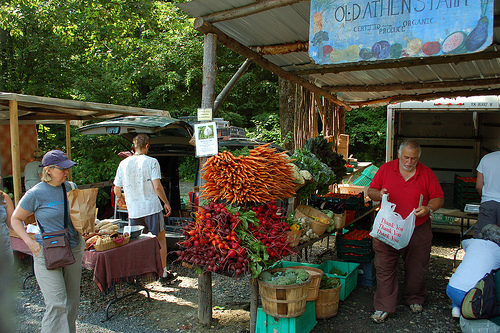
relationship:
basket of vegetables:
[256, 268, 308, 315] [258, 268, 308, 284]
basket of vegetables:
[279, 265, 321, 302] [298, 263, 320, 277]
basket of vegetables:
[311, 276, 339, 317] [320, 269, 339, 289]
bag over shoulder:
[35, 179, 76, 269] [29, 178, 77, 193]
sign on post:
[196, 105, 210, 155] [197, 31, 217, 324]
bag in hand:
[371, 192, 418, 252] [412, 202, 429, 217]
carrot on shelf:
[231, 152, 251, 171] [225, 193, 305, 211]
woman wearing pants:
[10, 147, 87, 332] [36, 246, 88, 329]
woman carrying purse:
[10, 147, 87, 329] [35, 182, 77, 271]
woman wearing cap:
[10, 147, 87, 329] [42, 149, 77, 169]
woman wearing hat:
[10, 147, 87, 329] [41, 147, 74, 167]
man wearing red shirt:
[367, 139, 444, 323] [368, 157, 443, 227]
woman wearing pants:
[10, 147, 87, 332] [29, 236, 91, 331]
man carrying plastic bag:
[357, 130, 439, 332] [369, 192, 421, 257]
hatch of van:
[74, 111, 197, 146] [93, 141, 199, 219]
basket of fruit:
[256, 268, 311, 318] [258, 269, 307, 284]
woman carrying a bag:
[10, 147, 87, 329] [66, 186, 98, 231]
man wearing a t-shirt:
[112, 132, 180, 284] [112, 151, 161, 221]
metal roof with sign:
[225, 11, 297, 49] [304, 0, 493, 73]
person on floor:
[443, 222, 498, 314] [18, 264, 486, 331]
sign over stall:
[306, 0, 497, 67] [216, 2, 498, 324]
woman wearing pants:
[10, 147, 87, 332] [18, 235, 105, 330]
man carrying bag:
[367, 139, 444, 323] [370, 190, 416, 249]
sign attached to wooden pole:
[192, 108, 218, 158] [197, 19, 215, 324]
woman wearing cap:
[10, 147, 87, 329] [34, 144, 90, 170]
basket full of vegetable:
[256, 268, 311, 318] [261, 265, 308, 290]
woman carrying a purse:
[10, 147, 87, 329] [36, 224, 76, 269]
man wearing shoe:
[367, 139, 444, 323] [368, 301, 395, 323]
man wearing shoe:
[367, 139, 444, 323] [402, 300, 430, 311]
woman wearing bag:
[10, 147, 87, 329] [35, 179, 76, 269]